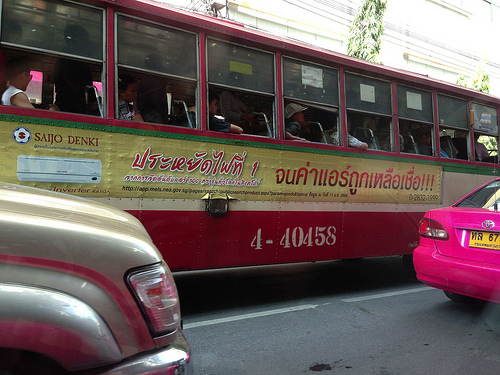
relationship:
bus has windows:
[0, 0, 489, 267] [2, 5, 204, 127]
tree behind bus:
[350, 2, 389, 62] [0, 0, 489, 267]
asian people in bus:
[122, 45, 167, 122] [0, 0, 489, 267]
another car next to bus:
[1, 174, 186, 370] [0, 0, 489, 267]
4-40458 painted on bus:
[249, 223, 340, 254] [0, 0, 489, 267]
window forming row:
[2, 0, 110, 117] [1, 1, 484, 164]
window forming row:
[113, 11, 201, 129] [1, 1, 484, 164]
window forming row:
[205, 36, 279, 138] [1, 1, 484, 164]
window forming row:
[281, 55, 344, 147] [1, 1, 484, 164]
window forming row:
[342, 70, 392, 150] [1, 1, 484, 164]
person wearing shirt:
[9, 61, 39, 108] [1, 84, 26, 106]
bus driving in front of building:
[0, 0, 489, 267] [240, 4, 479, 84]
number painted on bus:
[249, 227, 264, 251] [0, 0, 489, 267]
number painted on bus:
[278, 225, 291, 249] [0, 0, 489, 267]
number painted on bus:
[289, 224, 303, 247] [0, 0, 489, 267]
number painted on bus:
[301, 224, 314, 246] [0, 0, 489, 267]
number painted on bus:
[312, 224, 325, 245] [0, 0, 489, 267]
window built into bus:
[2, 0, 110, 117] [0, 0, 489, 267]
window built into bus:
[113, 11, 201, 129] [0, 0, 489, 267]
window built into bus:
[205, 36, 279, 138] [0, 0, 489, 267]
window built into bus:
[281, 55, 344, 147] [0, 0, 489, 267]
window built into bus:
[342, 70, 392, 150] [0, 0, 489, 267]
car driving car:
[1, 172, 199, 368] [411, 177, 484, 303]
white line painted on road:
[187, 304, 359, 329] [181, 253, 484, 370]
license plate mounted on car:
[466, 227, 499, 254] [411, 177, 484, 303]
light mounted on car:
[416, 211, 451, 240] [411, 177, 484, 303]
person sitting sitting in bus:
[113, 73, 136, 121] [0, 0, 489, 267]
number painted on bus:
[323, 222, 336, 244] [0, 0, 489, 267]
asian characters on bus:
[130, 143, 263, 177] [41, 14, 453, 312]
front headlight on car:
[122, 263, 196, 347] [0, 182, 191, 375]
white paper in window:
[297, 62, 333, 93] [163, 30, 370, 151]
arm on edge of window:
[224, 115, 253, 138] [163, 35, 319, 153]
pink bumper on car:
[413, 242, 499, 302] [399, 159, 497, 302]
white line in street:
[187, 304, 359, 329] [285, 306, 406, 355]